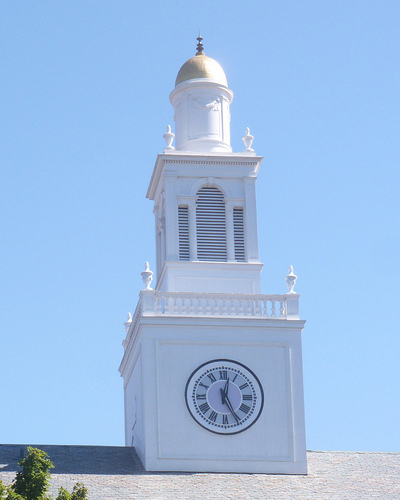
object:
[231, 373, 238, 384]
number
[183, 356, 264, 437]
clock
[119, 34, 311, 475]
tower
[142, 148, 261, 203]
roof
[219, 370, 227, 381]
number 12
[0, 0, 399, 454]
sky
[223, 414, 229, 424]
number 6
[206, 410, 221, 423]
number 7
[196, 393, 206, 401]
number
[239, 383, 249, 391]
number 2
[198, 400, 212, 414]
number 8